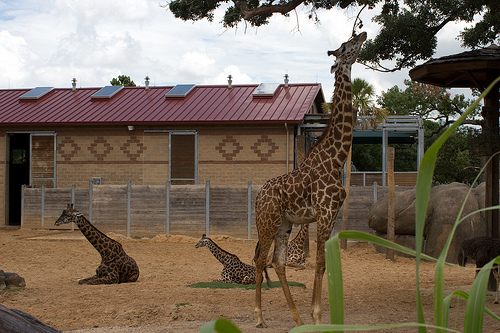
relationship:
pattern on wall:
[56, 135, 145, 160] [58, 126, 295, 182]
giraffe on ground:
[188, 228, 263, 283] [2, 221, 485, 325]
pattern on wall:
[198, 132, 288, 162] [197, 128, 293, 181]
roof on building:
[0, 83, 330, 123] [0, 82, 328, 226]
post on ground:
[384, 143, 397, 262] [2, 221, 485, 325]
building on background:
[7, 85, 326, 184] [1, 81, 490, 174]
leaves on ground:
[323, 79, 498, 328] [2, 221, 485, 325]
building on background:
[0, 73, 425, 233] [10, 80, 491, 160]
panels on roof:
[18, 85, 54, 100] [0, 83, 330, 123]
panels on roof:
[93, 82, 123, 103] [0, 83, 330, 123]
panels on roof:
[164, 80, 199, 100] [0, 83, 330, 123]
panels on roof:
[250, 80, 284, 97] [0, 83, 330, 123]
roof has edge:
[0, 83, 330, 123] [130, 112, 210, 127]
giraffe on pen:
[239, 19, 378, 331] [3, 107, 478, 314]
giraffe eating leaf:
[249, 29, 371, 332] [351, 12, 367, 33]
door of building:
[5, 133, 30, 224] [0, 82, 328, 226]